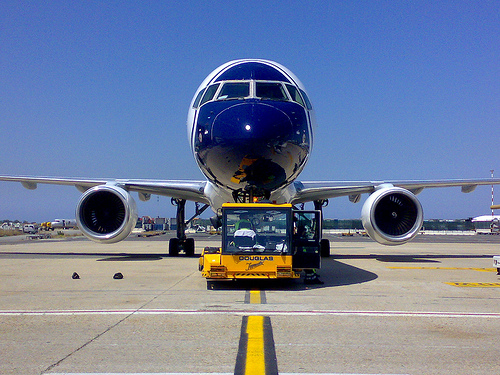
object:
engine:
[359, 185, 424, 246]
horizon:
[0, 212, 499, 224]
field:
[0, 229, 499, 374]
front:
[185, 57, 314, 201]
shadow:
[323, 254, 499, 263]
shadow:
[0, 250, 202, 262]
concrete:
[0, 230, 499, 374]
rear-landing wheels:
[180, 238, 198, 258]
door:
[288, 206, 323, 269]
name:
[236, 254, 274, 262]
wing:
[0, 172, 208, 209]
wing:
[299, 176, 499, 246]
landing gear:
[165, 198, 196, 258]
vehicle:
[198, 202, 331, 290]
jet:
[0, 58, 499, 257]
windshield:
[213, 80, 248, 101]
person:
[232, 221, 266, 252]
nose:
[208, 97, 300, 178]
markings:
[243, 314, 266, 374]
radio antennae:
[488, 169, 494, 215]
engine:
[73, 183, 138, 244]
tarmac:
[0, 230, 498, 374]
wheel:
[166, 236, 183, 256]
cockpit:
[190, 80, 313, 110]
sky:
[0, 0, 499, 226]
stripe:
[230, 314, 278, 375]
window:
[283, 83, 298, 106]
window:
[253, 80, 286, 101]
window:
[213, 79, 252, 100]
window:
[196, 82, 220, 105]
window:
[190, 85, 206, 109]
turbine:
[372, 192, 420, 235]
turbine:
[76, 189, 123, 235]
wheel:
[316, 238, 331, 256]